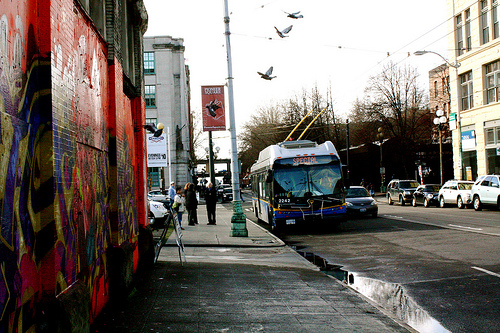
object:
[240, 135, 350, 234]
bus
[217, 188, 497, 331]
road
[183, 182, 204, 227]
people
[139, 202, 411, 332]
sidewalk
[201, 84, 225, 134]
red sign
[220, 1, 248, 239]
pole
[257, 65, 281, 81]
bird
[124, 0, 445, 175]
sky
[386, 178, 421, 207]
cars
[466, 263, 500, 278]
white line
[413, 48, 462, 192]
light post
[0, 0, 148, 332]
wall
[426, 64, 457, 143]
building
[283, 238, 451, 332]
puddle of water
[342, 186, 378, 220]
car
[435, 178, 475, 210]
car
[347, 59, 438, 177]
tree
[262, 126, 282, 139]
leaves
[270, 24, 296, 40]
birds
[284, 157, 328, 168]
electronic sign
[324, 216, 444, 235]
shadow